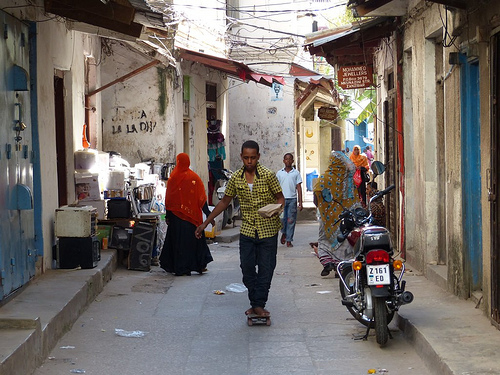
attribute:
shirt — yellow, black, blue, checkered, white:
[222, 165, 286, 238]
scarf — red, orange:
[168, 148, 208, 232]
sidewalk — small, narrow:
[4, 247, 118, 367]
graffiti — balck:
[112, 110, 160, 142]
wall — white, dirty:
[103, 43, 182, 199]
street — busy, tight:
[57, 207, 440, 366]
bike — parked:
[330, 184, 411, 344]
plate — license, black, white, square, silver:
[365, 265, 392, 290]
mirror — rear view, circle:
[317, 187, 337, 201]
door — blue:
[460, 50, 483, 304]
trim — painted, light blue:
[457, 54, 484, 295]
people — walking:
[160, 132, 376, 335]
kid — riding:
[193, 138, 291, 307]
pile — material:
[57, 141, 170, 281]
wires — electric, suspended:
[146, 0, 357, 65]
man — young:
[275, 149, 305, 247]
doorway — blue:
[456, 52, 487, 293]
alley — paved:
[29, 189, 435, 367]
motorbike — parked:
[330, 181, 423, 348]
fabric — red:
[163, 152, 208, 240]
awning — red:
[179, 45, 290, 86]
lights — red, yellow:
[353, 249, 404, 272]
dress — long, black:
[156, 212, 208, 277]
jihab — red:
[162, 150, 209, 229]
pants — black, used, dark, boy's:
[240, 236, 281, 305]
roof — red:
[294, 61, 334, 87]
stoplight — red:
[364, 249, 389, 268]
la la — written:
[110, 115, 139, 137]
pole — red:
[395, 83, 405, 173]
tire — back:
[370, 293, 397, 352]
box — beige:
[50, 203, 96, 241]